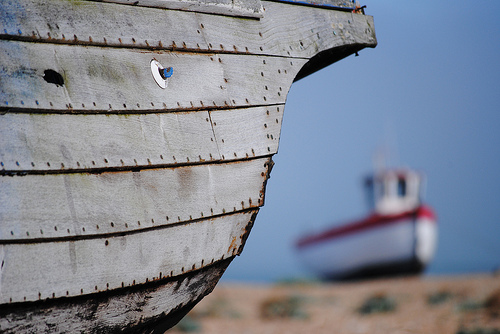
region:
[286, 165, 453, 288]
the boat is red, white and blue.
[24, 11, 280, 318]
The boat has wood panels.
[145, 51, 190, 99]
The hole is patched up.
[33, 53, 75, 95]
The hole is small.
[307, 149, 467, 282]
The boat is small.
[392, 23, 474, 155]
The sky is clear.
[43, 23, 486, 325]
The boats are on the shore.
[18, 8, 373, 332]
This boat is older.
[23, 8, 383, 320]
The boat is distressed.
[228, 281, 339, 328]
The sand is rocky.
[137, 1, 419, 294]
edge of a boat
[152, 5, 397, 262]
corner of a boat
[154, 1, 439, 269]
edge of an old boat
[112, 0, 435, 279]
corner of an old boat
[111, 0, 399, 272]
tip of a boat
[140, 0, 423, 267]
the tip of an old boat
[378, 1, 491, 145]
part of blue sky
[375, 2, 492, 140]
part of clear blue sky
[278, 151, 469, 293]
boat in the background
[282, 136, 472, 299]
large boat in background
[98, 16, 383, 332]
Abandon boats on shore.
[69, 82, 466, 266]
Abandon boats on shore.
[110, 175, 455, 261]
Abandon boats on shore.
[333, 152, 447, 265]
red and white boat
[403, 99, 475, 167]
blue sky in the background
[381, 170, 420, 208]
window on the boat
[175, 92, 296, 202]
front of the boat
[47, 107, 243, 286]
gray ship on ground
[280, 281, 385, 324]
brown dirt on ground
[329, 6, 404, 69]
tip of the ship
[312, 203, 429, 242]
red rim of ship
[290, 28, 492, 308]
blurry background of photo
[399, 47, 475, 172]
sky is blue and clear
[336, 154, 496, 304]
sky is blue and clear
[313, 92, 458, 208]
sky is blue and clear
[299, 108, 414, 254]
sky is blue and clear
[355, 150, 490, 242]
sky is blue and clear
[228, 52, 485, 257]
sky is blue and clear